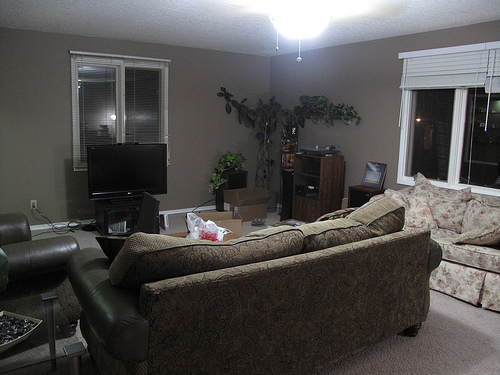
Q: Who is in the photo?
A: Nobody is.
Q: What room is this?
A: Living room.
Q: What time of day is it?
A: Evening.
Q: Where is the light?
A: Hanging from the ceiling.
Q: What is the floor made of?
A: Carpet.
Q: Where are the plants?
A: In the corner.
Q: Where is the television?
A: On a stand.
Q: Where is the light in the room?
A: Ceiling light.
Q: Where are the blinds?
A: On windows.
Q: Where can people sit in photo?
A: Sofas and chair.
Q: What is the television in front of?
A: A window.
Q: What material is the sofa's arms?
A: Leather.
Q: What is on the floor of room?
A: Carpet.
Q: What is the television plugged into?
A: Outlet.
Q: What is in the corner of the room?
A: Plant.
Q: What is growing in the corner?
A: Plant.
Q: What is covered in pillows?
A: Sofa.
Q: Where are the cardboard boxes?
A: Floor.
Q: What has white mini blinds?
A: Windows.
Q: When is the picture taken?
A: Nighttime.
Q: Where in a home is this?
A: Living room.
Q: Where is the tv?
A: Under the window.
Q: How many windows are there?
A: 4.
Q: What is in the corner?
A: A plant.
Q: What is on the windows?
A: Blinds.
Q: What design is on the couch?
A: Floral.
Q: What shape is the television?
A: Rectangle.